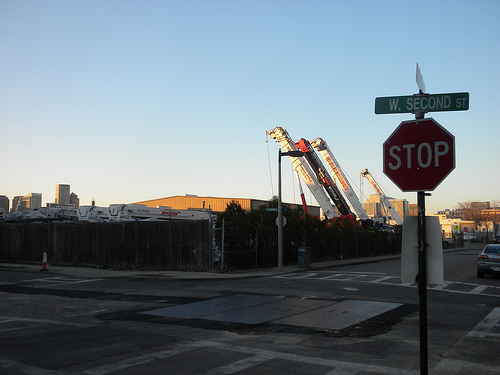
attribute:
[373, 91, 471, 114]
sign — at intersection, green, white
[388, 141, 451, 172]
lettering — white, block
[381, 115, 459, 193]
sign — octagonal, red, at intersection, read, white, at a street crossing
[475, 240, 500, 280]
toyota — pewter, silver, on the road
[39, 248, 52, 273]
cone — orange, on street, for safety, small, white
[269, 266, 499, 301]
crosswalk — white, fading, in city, on street, on a road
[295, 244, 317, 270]
can — dark gray, plastic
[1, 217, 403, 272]
fence — wooden, long, brown, for privacy, wood, chain link, for security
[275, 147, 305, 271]
streetlight — large, grey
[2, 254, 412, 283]
sidewalk — concrete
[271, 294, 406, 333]
hole covers — metal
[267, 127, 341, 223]
cranes — for construction, parked, grouped, big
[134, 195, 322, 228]
building — in the distance, for construction, for warehouse use, metal, large, brown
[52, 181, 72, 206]
buildings — in the distance, tall, large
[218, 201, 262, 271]
shrubs — large, green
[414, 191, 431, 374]
post — metal